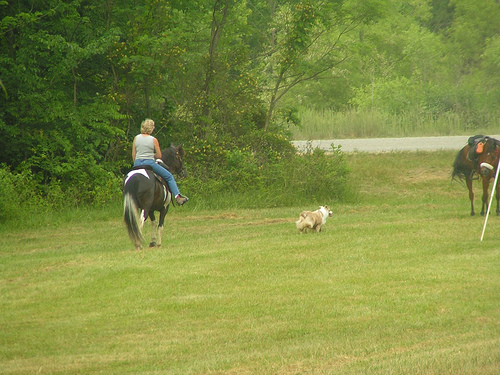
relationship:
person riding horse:
[131, 118, 188, 205] [103, 145, 228, 215]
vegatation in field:
[12, 142, 364, 232] [0, 146, 500, 373]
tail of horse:
[121, 190, 143, 244] [128, 170, 167, 235]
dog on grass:
[295, 204, 333, 233] [0, 150, 499, 374]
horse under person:
[121, 143, 186, 251] [126, 118, 188, 199]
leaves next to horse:
[1, 0, 313, 205] [122, 144, 188, 249]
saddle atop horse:
[467, 132, 497, 164] [453, 135, 499, 219]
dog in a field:
[294, 200, 333, 232] [0, 146, 500, 373]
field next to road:
[0, 146, 500, 373] [284, 133, 499, 153]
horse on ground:
[120, 170, 171, 248] [0, 209, 498, 373]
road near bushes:
[284, 127, 496, 158] [210, 105, 287, 210]